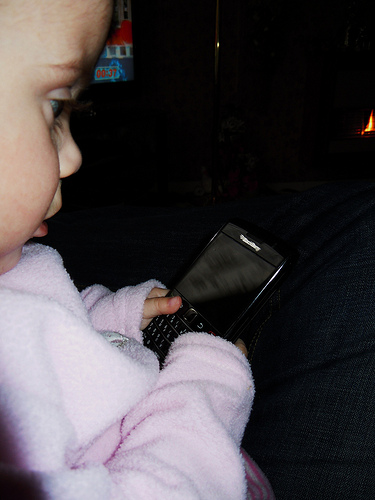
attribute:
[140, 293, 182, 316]
thumb — girl's 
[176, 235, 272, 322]
screen — blank blackberry, reflecting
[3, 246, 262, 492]
shirt — pink fleece sweat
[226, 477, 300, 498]
pants — denim, leg clad 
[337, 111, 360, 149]
fireplace — fire burning 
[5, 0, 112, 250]
face — baby 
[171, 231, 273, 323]
screen — television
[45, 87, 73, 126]
eye — baby , long eyelashes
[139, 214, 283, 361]
cellphone — shiny, black, blackberry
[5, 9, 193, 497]
baby — small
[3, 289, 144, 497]
fabric — fluffy, pink, towel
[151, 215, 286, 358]
cellphone — blackberry, being held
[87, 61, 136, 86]
tv screen — 37 seconds on it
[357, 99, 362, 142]
light — orange, off to the right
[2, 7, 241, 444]
child — small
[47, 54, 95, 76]
eyebrow — thin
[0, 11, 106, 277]
head — babies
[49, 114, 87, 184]
nose — toddlers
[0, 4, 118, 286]
face — small 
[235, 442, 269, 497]
bottoms — pink-and-white, striped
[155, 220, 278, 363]
phone — blackberry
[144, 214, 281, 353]
phone — blackberry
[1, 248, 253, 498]
clothes — pink, fuzzy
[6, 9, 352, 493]
shot — back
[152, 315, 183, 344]
buttons — several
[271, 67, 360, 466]
room — lit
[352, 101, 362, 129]
fireplace — lit